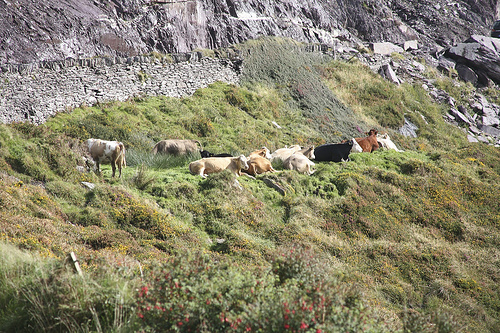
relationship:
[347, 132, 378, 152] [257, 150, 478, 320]
cow on hill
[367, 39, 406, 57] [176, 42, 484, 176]
rock on hill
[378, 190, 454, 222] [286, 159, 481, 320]
flowers on bushes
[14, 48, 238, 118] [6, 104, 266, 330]
wall near hill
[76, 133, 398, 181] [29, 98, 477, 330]
cows on hill